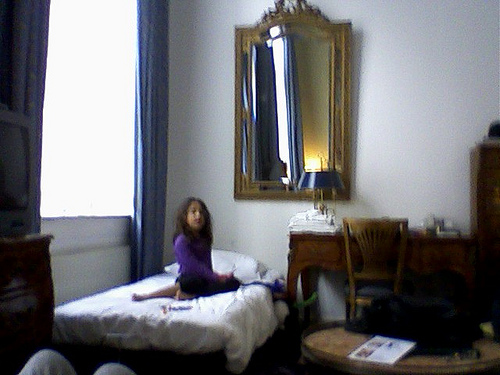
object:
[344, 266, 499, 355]
backpack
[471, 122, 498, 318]
dresser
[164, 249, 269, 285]
pillow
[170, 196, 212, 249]
hair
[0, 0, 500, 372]
room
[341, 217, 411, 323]
desk chair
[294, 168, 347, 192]
lampshade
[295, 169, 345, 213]
lamp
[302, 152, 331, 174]
lamb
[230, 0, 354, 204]
mirror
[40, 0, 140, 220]
window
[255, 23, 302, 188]
reflection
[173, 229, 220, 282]
purple shirt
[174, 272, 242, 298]
pants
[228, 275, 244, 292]
knees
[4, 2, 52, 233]
curtains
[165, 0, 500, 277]
wall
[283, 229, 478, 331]
desk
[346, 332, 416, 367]
material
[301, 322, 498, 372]
table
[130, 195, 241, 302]
girl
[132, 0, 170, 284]
drapes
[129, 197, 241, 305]
person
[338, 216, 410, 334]
chair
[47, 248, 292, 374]
bed